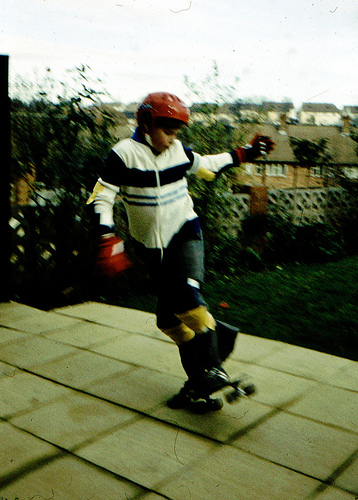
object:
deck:
[0, 297, 356, 500]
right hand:
[96, 230, 130, 275]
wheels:
[171, 377, 252, 410]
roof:
[203, 122, 356, 166]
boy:
[87, 91, 277, 397]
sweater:
[85, 126, 243, 258]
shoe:
[204, 351, 231, 383]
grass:
[99, 238, 358, 361]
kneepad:
[176, 305, 217, 333]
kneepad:
[159, 321, 195, 341]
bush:
[0, 61, 258, 298]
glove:
[93, 233, 131, 276]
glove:
[234, 131, 273, 166]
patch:
[195, 166, 216, 182]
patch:
[86, 179, 103, 205]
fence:
[198, 185, 357, 240]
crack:
[21, 350, 137, 390]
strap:
[142, 133, 161, 155]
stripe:
[100, 147, 194, 186]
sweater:
[86, 136, 244, 248]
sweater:
[104, 143, 201, 241]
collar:
[126, 125, 155, 149]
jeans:
[147, 220, 220, 374]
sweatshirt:
[82, 134, 235, 260]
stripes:
[115, 182, 187, 210]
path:
[108, 236, 358, 366]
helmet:
[136, 92, 190, 126]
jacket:
[91, 124, 239, 268]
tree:
[12, 78, 89, 169]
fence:
[0, 200, 117, 304]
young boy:
[113, 86, 251, 389]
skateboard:
[166, 370, 255, 412]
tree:
[15, 107, 120, 271]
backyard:
[0, 160, 358, 500]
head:
[135, 86, 189, 152]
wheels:
[194, 384, 257, 417]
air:
[0, 1, 353, 500]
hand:
[99, 234, 133, 276]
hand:
[235, 133, 276, 164]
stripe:
[207, 367, 228, 385]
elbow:
[192, 164, 217, 184]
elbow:
[86, 177, 103, 206]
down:
[118, 223, 240, 394]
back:
[150, 435, 323, 500]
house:
[0, 115, 358, 500]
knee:
[179, 296, 213, 337]